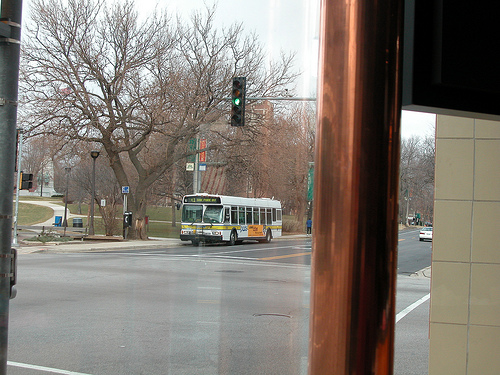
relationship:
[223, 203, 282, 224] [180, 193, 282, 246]
windows on bus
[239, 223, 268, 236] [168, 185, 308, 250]
advertisement on bus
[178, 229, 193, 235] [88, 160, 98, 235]
light on pole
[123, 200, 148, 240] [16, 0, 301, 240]
trunk of tree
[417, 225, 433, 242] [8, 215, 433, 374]
car in pavement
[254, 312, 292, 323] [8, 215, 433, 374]
manhole cover on pavement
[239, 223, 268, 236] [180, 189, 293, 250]
advertisement on bus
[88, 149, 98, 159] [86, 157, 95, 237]
light on pole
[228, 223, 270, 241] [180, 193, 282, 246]
advertisement on bus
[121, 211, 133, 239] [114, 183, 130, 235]
booth on pole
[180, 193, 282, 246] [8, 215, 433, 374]
bus on side of pavement